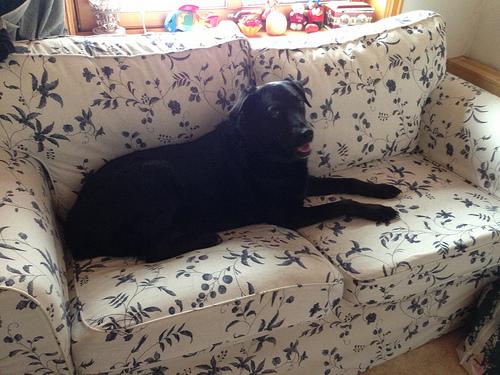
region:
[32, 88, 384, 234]
the dog is black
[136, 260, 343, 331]
the sofa is decorated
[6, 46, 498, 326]
the dog is on the soffa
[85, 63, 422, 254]
the dog is facing the camera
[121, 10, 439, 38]
there are toys on the window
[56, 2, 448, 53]
the window has light coming on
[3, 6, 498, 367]
the photo was taken during the day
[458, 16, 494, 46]
the wall is white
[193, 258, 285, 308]
there are branches on the sofa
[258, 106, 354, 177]
the dog has its open mouth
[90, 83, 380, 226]
Black dog sitting on couch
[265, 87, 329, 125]
Dog has dark eyes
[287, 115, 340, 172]
Dog has black nose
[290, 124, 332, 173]
Dog has pink tongue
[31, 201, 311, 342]
Love seat is white and blue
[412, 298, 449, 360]
Carpet is tan under couch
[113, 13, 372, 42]
Many decorations on window sill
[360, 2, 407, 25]
Window frame is brown wood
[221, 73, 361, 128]
Dog's ears are black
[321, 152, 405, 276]
Dog has black legs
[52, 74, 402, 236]
black dog laying down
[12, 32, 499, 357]
flower pattern couch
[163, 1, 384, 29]
trinkets in a window seal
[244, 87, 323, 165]
dog with its mouth open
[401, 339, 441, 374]
Carpet on the floor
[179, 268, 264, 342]
white and blue fabric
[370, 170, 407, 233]
Dog paws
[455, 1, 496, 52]
white on the walls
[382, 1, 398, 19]
wooden window seal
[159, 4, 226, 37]
a fish figurine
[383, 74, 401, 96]
a small grey flower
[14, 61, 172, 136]
a grey and white pattern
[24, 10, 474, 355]
a dog sitting on a couch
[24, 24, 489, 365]
black and white loveseat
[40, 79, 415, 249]
a full grown lab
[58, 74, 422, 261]
a black dog laying down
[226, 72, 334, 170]
a dog with his mouth open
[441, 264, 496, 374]
a shopping bag on ground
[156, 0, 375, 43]
an assortment of small objects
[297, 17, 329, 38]
a red tomato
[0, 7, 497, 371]
black dog sitting on a couch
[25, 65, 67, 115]
dark flower design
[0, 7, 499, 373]
white couch with black floral designs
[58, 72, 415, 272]
black dog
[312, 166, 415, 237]
front paws of a black dog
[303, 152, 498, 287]
black and white couch cushion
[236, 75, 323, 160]
a black dog's head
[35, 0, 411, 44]
knick knacks on a windowsill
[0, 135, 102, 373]
armrest of a couch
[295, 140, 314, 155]
a dog's tongue